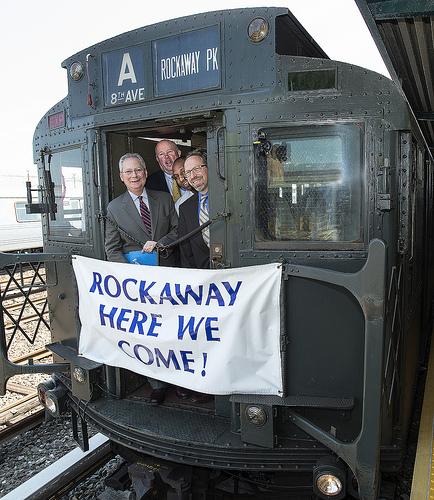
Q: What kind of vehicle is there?
A: A train.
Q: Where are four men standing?
A: On back of a train.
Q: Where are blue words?
A: On white sign.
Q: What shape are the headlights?
A: Round.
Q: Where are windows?
A: On the train.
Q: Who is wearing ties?
A: The men.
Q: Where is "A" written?
A: On top of train.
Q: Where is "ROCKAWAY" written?
A: On white sign.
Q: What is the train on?
A: Train tracks.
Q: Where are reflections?
A: On right window.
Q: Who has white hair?
A: Man on the left.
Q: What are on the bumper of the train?
A: The lights.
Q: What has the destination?
A: The train marque.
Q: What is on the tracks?
A: The train.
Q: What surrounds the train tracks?
A: Gravel.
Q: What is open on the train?
A: The back door.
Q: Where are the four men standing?
A: Doorway.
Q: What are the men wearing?
A: Suits and ties.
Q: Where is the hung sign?
A: On the train.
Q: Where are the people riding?
A: On train car.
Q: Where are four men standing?
A: In train doorway.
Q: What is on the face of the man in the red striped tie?
A: Eyeglasses.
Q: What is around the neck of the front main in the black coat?
A: A brown and white tie.